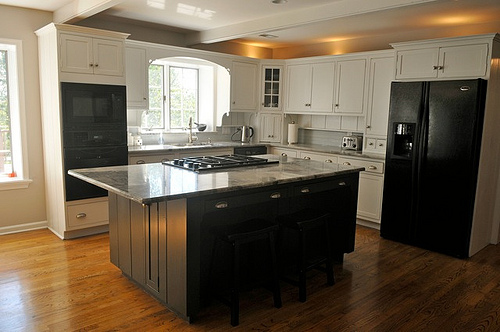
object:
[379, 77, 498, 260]
refrigerator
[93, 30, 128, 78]
cabinet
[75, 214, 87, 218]
handle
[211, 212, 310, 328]
stool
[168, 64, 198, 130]
window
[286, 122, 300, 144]
paper towels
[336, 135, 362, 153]
toaster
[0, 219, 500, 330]
floor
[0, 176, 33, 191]
windowsill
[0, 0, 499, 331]
kitchen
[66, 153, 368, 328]
island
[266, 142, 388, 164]
counter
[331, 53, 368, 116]
cabinets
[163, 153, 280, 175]
stove burner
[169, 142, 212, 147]
sink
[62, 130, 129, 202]
oven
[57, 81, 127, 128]
microwave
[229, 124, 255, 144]
coffee maker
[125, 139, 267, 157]
counter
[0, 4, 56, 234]
wall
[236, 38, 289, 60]
light